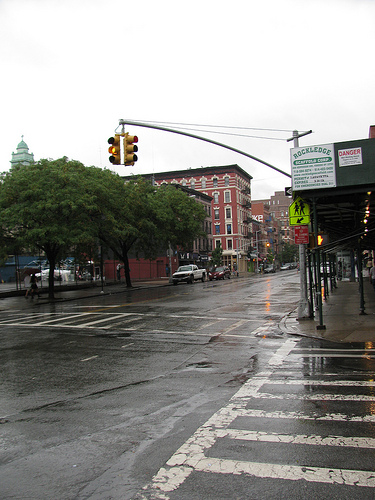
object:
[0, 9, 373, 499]
scene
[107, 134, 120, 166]
street light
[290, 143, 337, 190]
sign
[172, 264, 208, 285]
truck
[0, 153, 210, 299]
tree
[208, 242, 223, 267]
tree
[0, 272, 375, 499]
street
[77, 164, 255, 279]
building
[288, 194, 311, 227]
sign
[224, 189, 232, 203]
frame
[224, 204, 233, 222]
frame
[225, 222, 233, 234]
frame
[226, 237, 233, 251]
frame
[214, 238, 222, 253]
frame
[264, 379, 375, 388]
line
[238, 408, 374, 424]
line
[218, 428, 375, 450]
line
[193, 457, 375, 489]
line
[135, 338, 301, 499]
line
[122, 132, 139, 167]
traffic light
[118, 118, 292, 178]
post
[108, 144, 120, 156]
light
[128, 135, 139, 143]
light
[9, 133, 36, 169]
tower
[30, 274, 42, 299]
couple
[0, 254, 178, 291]
fence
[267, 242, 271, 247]
light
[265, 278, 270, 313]
reflection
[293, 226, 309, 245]
traffic sign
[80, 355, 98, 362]
lines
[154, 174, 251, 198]
decoration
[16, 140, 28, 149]
dome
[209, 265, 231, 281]
car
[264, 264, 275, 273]
car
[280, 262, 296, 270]
car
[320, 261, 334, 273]
car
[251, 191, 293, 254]
building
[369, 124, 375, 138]
building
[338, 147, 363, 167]
sign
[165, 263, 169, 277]
person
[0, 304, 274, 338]
crosswalk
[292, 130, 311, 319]
pole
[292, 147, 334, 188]
lettering